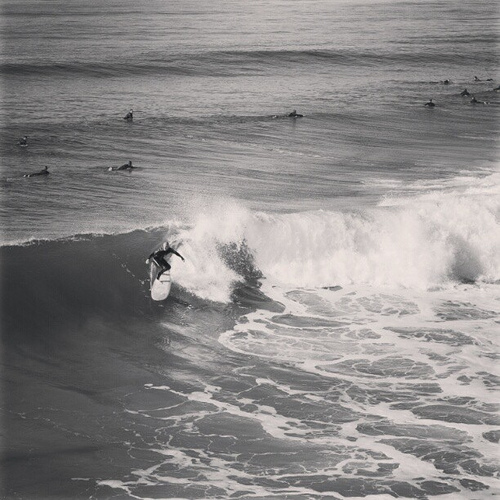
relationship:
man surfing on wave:
[145, 241, 185, 281] [3, 186, 498, 313]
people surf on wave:
[417, 70, 498, 116] [292, 166, 493, 275]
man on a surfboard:
[145, 241, 185, 281] [144, 272, 179, 307]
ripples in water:
[178, 330, 450, 486] [0, 3, 500, 498]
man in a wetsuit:
[129, 225, 199, 321] [131, 230, 188, 320]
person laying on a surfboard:
[93, 156, 145, 176] [107, 164, 144, 174]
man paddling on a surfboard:
[145, 241, 185, 281] [149, 260, 171, 301]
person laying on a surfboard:
[24, 156, 55, 175] [19, 170, 50, 180]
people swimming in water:
[425, 98, 436, 107] [0, 3, 500, 498]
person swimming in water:
[471, 96, 489, 104] [0, 3, 500, 498]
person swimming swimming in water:
[461, 85, 470, 96] [0, 3, 500, 498]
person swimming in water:
[124, 109, 133, 122] [0, 3, 500, 498]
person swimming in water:
[17, 136, 29, 147] [0, 3, 500, 498]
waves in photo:
[225, 203, 437, 303] [8, 26, 477, 494]